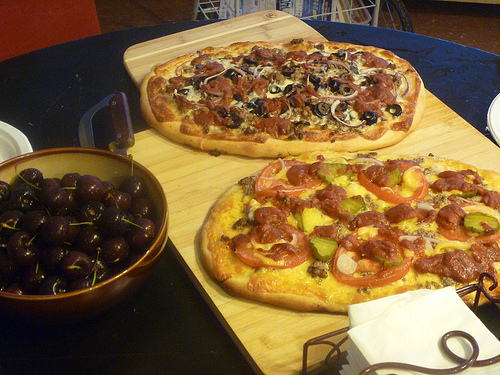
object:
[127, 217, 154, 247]
cherries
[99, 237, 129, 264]
cherries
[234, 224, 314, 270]
tomato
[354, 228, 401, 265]
red topping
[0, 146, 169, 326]
bowl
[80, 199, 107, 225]
cherry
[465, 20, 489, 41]
ground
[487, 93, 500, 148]
plate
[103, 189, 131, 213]
cherry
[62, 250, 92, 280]
cherry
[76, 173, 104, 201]
cherry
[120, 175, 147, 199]
cherry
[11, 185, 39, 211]
cherry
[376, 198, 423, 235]
pizza topping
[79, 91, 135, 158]
pizza cutter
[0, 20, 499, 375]
tablecloth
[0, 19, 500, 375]
table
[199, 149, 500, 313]
pizza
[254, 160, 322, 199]
tomato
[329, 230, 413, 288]
tomato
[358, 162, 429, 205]
tomato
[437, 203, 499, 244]
tomato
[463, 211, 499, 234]
pickle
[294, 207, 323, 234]
pickle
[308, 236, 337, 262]
pickle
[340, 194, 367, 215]
pickle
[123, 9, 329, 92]
boards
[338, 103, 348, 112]
olive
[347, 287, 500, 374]
paper napkins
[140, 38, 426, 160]
pizza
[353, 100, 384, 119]
meat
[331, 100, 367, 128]
onion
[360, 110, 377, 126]
black olives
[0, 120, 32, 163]
bowl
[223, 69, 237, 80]
olive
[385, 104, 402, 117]
olive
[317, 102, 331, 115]
olive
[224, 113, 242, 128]
olive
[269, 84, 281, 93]
olive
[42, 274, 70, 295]
fruit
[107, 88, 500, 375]
board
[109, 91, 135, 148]
handle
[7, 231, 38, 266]
cherry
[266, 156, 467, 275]
cheese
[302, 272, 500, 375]
rack